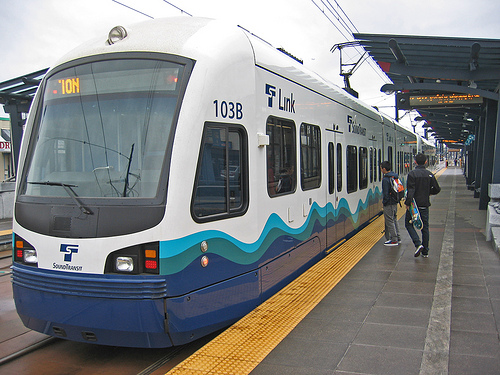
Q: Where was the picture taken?
A: It was taken at the station.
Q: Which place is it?
A: It is a station.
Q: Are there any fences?
A: No, there are no fences.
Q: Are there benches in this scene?
A: No, there are no benches.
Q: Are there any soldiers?
A: No, there are no soldiers.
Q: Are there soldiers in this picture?
A: No, there are no soldiers.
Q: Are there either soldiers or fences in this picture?
A: No, there are no soldiers or fences.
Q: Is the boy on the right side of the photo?
A: Yes, the boy is on the right of the image.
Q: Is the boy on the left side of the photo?
A: No, the boy is on the right of the image.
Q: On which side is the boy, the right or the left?
A: The boy is on the right of the image.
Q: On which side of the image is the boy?
A: The boy is on the right of the image.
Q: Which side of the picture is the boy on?
A: The boy is on the right of the image.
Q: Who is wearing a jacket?
A: The boy is wearing a jacket.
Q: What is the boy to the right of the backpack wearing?
A: The boy is wearing a jacket.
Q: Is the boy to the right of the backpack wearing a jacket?
A: Yes, the boy is wearing a jacket.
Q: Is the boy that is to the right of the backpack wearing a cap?
A: No, the boy is wearing a jacket.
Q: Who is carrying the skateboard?
A: The boy is carrying the skateboard.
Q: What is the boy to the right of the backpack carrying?
A: The boy is carrying a skateboard.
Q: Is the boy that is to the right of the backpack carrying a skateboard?
A: Yes, the boy is carrying a skateboard.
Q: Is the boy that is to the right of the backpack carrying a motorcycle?
A: No, the boy is carrying a skateboard.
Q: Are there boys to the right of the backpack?
A: Yes, there is a boy to the right of the backpack.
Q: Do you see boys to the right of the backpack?
A: Yes, there is a boy to the right of the backpack.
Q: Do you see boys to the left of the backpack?
A: No, the boy is to the right of the backpack.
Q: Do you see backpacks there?
A: Yes, there is a backpack.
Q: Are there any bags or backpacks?
A: Yes, there is a backpack.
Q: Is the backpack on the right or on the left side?
A: The backpack is on the right of the image.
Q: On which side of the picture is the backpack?
A: The backpack is on the right of the image.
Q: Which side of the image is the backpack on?
A: The backpack is on the right of the image.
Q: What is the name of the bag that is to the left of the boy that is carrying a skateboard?
A: The bag is a backpack.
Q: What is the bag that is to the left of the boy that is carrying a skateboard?
A: The bag is a backpack.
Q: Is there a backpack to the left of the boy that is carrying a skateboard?
A: Yes, there is a backpack to the left of the boy.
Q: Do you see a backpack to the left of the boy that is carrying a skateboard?
A: Yes, there is a backpack to the left of the boy.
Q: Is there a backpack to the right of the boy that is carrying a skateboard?
A: No, the backpack is to the left of the boy.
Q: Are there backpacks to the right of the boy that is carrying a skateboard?
A: No, the backpack is to the left of the boy.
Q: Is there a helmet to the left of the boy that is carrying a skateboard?
A: No, there is a backpack to the left of the boy.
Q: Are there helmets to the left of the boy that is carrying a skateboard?
A: No, there is a backpack to the left of the boy.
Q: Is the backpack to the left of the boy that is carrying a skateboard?
A: Yes, the backpack is to the left of the boy.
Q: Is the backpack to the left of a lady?
A: No, the backpack is to the left of the boy.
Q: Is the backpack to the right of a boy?
A: No, the backpack is to the left of a boy.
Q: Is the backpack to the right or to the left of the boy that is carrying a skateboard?
A: The backpack is to the left of the boy.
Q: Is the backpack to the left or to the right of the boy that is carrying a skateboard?
A: The backpack is to the left of the boy.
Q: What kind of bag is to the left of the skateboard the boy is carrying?
A: The bag is a backpack.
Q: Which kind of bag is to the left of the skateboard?
A: The bag is a backpack.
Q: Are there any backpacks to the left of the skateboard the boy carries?
A: Yes, there is a backpack to the left of the skateboard.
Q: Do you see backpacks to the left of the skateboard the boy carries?
A: Yes, there is a backpack to the left of the skateboard.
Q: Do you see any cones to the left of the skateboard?
A: No, there is a backpack to the left of the skateboard.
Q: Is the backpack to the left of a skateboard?
A: Yes, the backpack is to the left of a skateboard.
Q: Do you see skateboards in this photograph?
A: Yes, there is a skateboard.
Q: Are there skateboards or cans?
A: Yes, there is a skateboard.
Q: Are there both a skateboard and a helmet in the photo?
A: No, there is a skateboard but no helmets.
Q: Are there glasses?
A: No, there are no glasses.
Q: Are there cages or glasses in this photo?
A: No, there are no glasses or cages.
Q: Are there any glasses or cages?
A: No, there are no glasses or cages.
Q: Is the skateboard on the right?
A: Yes, the skateboard is on the right of the image.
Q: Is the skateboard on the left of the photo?
A: No, the skateboard is on the right of the image.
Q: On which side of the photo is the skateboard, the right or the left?
A: The skateboard is on the right of the image.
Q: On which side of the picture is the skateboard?
A: The skateboard is on the right of the image.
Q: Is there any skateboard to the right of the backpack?
A: Yes, there is a skateboard to the right of the backpack.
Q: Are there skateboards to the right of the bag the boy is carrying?
A: Yes, there is a skateboard to the right of the backpack.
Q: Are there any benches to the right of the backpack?
A: No, there is a skateboard to the right of the backpack.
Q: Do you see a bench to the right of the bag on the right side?
A: No, there is a skateboard to the right of the backpack.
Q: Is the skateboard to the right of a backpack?
A: Yes, the skateboard is to the right of a backpack.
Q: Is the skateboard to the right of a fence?
A: No, the skateboard is to the right of a backpack.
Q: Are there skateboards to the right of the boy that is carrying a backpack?
A: Yes, there is a skateboard to the right of the boy.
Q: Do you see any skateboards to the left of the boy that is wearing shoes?
A: No, the skateboard is to the right of the boy.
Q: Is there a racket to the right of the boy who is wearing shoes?
A: No, there is a skateboard to the right of the boy.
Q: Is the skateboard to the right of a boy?
A: Yes, the skateboard is to the right of a boy.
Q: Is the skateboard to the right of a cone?
A: No, the skateboard is to the right of a boy.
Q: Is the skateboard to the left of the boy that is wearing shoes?
A: No, the skateboard is to the right of the boy.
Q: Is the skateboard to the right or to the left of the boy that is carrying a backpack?
A: The skateboard is to the right of the boy.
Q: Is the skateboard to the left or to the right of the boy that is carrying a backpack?
A: The skateboard is to the right of the boy.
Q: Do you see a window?
A: Yes, there is a window.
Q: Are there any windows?
A: Yes, there is a window.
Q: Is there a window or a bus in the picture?
A: Yes, there is a window.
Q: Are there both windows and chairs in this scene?
A: No, there is a window but no chairs.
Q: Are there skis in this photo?
A: No, there are no skis.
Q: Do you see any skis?
A: No, there are no skis.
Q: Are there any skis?
A: No, there are no skis.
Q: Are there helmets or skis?
A: No, there are no skis or helmets.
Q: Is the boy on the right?
A: Yes, the boy is on the right of the image.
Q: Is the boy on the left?
A: No, the boy is on the right of the image.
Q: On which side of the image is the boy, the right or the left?
A: The boy is on the right of the image.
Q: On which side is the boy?
A: The boy is on the right of the image.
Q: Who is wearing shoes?
A: The boy is wearing shoes.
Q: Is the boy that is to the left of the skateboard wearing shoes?
A: Yes, the boy is wearing shoes.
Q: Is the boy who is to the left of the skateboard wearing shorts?
A: No, the boy is wearing shoes.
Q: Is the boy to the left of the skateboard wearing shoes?
A: Yes, the boy is wearing shoes.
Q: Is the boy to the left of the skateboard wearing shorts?
A: No, the boy is wearing shoes.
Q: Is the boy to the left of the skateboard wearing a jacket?
A: Yes, the boy is wearing a jacket.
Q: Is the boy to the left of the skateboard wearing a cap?
A: No, the boy is wearing a jacket.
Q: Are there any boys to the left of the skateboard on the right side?
A: Yes, there is a boy to the left of the skateboard.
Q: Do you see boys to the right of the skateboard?
A: No, the boy is to the left of the skateboard.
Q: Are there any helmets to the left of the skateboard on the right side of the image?
A: No, there is a boy to the left of the skateboard.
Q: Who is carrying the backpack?
A: The boy is carrying the backpack.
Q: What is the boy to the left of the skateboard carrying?
A: The boy is carrying a backpack.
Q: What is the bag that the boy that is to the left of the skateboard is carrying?
A: The bag is a backpack.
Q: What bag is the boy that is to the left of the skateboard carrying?
A: The boy is carrying a backpack.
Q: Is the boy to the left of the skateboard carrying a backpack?
A: Yes, the boy is carrying a backpack.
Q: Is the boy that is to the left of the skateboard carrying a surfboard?
A: No, the boy is carrying a backpack.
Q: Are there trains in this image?
A: Yes, there is a train.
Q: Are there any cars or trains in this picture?
A: Yes, there is a train.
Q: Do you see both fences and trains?
A: No, there is a train but no fences.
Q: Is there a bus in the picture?
A: No, there are no buses.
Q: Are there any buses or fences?
A: No, there are no buses or fences.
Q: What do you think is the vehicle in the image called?
A: The vehicle is a train.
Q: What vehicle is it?
A: The vehicle is a train.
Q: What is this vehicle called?
A: That is a train.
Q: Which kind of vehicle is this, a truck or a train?
A: That is a train.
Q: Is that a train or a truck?
A: That is a train.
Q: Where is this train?
A: The train is at the station.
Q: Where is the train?
A: The train is at the station.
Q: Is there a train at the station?
A: Yes, there is a train at the station.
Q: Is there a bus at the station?
A: No, there is a train at the station.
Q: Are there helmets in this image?
A: No, there are no helmets.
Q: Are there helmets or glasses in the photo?
A: No, there are no helmets or glasses.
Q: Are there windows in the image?
A: Yes, there is a window.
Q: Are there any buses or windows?
A: Yes, there is a window.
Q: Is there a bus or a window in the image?
A: Yes, there is a window.